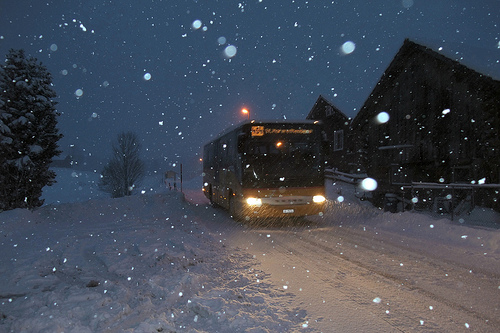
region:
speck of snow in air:
[353, 176, 382, 206]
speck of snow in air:
[272, 279, 292, 298]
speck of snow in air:
[134, 70, 154, 93]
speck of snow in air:
[363, 289, 384, 303]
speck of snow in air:
[171, 285, 188, 300]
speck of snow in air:
[423, 302, 436, 312]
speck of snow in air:
[64, 255, 82, 269]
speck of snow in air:
[336, 32, 361, 59]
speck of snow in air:
[263, 53, 280, 68]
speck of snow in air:
[291, 21, 301, 30]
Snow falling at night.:
[110, 20, 357, 86]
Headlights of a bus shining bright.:
[242, 190, 332, 209]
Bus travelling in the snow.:
[201, 118, 331, 225]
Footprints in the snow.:
[136, 218, 201, 322]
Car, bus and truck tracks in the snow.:
[344, 247, 496, 322]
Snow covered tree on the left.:
[7, 52, 52, 210]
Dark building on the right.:
[355, 32, 496, 233]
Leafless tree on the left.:
[97, 127, 149, 197]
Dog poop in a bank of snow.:
[87, 269, 99, 290]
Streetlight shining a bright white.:
[239, 104, 256, 116]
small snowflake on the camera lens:
[338, 35, 365, 61]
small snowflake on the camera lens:
[356, 173, 386, 193]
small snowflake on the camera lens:
[340, 38, 357, 55]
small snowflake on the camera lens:
[222, 42, 240, 60]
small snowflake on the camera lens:
[192, 12, 204, 33]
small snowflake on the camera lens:
[140, 67, 153, 81]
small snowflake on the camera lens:
[71, 84, 88, 99]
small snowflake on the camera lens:
[137, 182, 149, 198]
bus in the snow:
[186, 106, 345, 228]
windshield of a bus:
[242, 131, 327, 195]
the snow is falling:
[93, 43, 166, 204]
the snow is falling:
[370, 152, 461, 283]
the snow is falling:
[86, 109, 196, 263]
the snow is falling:
[273, 22, 421, 125]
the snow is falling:
[111, 154, 258, 296]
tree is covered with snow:
[7, 49, 89, 224]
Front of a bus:
[238, 122, 333, 216]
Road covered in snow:
[325, 219, 495, 327]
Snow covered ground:
[21, 198, 178, 330]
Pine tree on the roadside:
[0, 49, 62, 206]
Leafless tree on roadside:
[105, 133, 144, 197]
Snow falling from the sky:
[60, 7, 357, 97]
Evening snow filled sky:
[59, 4, 367, 98]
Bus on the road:
[198, 124, 322, 219]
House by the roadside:
[358, 41, 499, 203]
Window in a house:
[331, 129, 346, 150]